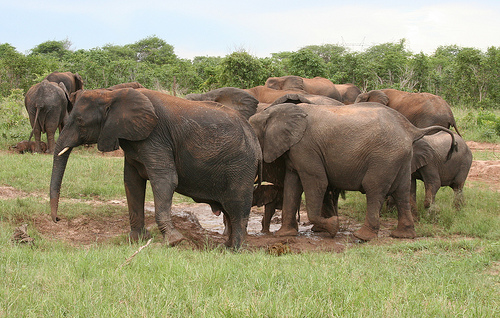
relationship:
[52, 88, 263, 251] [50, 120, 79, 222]
elephant has a trunk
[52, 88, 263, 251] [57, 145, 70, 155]
elephant has a tusk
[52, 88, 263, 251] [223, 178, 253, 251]
elephant has back legs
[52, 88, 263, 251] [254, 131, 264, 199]
elephant has a tail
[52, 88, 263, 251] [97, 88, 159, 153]
elephant has an ear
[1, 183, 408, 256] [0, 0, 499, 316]
mud in field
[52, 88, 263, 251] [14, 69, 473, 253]
elephant in a herd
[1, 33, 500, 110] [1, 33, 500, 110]
trees have leaves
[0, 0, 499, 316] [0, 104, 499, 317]
field has grass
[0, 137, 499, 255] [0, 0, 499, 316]
dirt in field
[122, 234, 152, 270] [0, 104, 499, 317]
stick on grass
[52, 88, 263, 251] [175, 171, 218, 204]
elephant has a stomach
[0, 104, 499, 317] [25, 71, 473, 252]
grass around elephants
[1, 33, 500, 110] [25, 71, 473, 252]
trees behind elephants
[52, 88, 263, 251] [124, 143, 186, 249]
elephant has front legs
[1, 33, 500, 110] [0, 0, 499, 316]
trees in field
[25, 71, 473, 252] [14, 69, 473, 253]
elephants in a herd